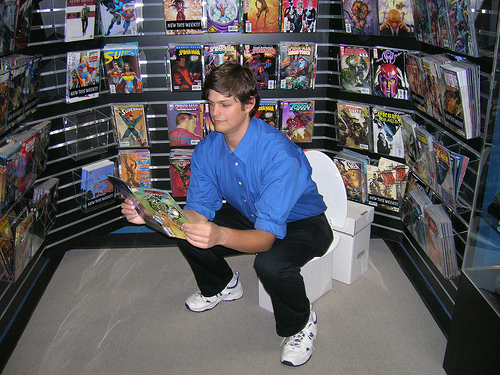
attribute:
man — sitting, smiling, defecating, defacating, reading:
[121, 56, 332, 368]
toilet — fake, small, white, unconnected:
[253, 148, 376, 314]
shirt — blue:
[179, 115, 330, 237]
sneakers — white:
[184, 273, 328, 367]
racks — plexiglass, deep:
[0, 1, 499, 307]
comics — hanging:
[332, 1, 481, 281]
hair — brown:
[198, 62, 259, 115]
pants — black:
[173, 197, 333, 335]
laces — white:
[278, 329, 317, 351]